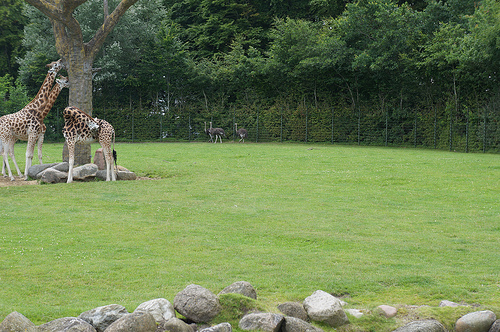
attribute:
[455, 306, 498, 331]
stone — large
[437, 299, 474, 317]
stone — large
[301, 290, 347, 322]
stone — large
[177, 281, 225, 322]
stone — large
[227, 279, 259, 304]
stone — large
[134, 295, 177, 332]
stone — large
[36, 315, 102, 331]
stone — large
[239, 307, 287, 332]
stone — large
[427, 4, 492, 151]
tree — tall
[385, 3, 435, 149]
tree — tall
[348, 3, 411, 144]
tree — tall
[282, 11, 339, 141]
tree — tall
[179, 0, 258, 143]
tree — tall